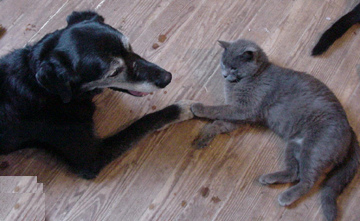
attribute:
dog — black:
[5, 8, 182, 183]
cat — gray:
[157, 22, 351, 186]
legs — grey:
[196, 95, 294, 165]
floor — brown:
[140, 7, 209, 45]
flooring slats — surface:
[2, 5, 358, 214]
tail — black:
[309, 1, 359, 54]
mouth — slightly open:
[125, 51, 190, 97]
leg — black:
[48, 91, 194, 189]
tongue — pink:
[129, 85, 148, 97]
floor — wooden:
[134, 5, 217, 69]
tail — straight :
[306, 4, 358, 57]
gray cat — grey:
[190, 39, 358, 219]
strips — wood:
[150, 168, 256, 197]